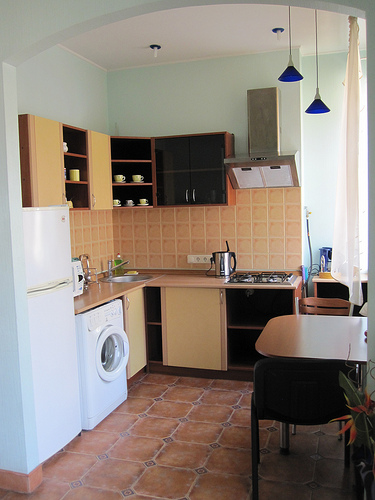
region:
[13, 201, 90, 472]
white refrigerator in the kitchen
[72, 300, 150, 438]
white dish washer in the kitch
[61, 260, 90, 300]
white microwave in the kitchen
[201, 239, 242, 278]
black and silver coffee maker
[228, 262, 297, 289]
black and silver gas stove in the kitchen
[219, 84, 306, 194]
white and silver vents over the stove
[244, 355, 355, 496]
black chair next to the table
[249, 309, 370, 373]
small wooden dining table by the window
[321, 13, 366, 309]
white curtains covering the windows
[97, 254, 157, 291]
silver and round sink on the counter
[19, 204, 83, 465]
a white upright two door refrigerator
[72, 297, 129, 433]
a white front load washing machine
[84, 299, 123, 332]
a white control panel with many buttons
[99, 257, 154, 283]
a silver kitchen sink and faucet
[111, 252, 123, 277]
a clear bottle of bright green soap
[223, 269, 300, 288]
stove burners set into a counter top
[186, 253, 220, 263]
a white electrical outlet in the wall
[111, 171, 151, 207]
yellow tea cups and saucers on a sheves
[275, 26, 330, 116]
blue lights hang down from the ceiling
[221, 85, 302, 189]
a silver stove vent hangs from a wall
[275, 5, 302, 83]
white and blue light fixture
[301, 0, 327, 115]
white and blue light fixture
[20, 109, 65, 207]
brown kitchen shelf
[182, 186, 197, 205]
kitchen shelf door handles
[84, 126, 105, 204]
brown kitchen shelf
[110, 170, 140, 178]
two teacups in kitchen shelf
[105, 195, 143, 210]
three teacups in kitchen shelf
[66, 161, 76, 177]
mug in kitchen shelf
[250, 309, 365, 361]
wooden table in kitchen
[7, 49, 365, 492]
a kitchen room scene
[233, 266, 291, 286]
gas stove cooktop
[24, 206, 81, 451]
a white refrigerator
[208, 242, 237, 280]
silver and black coffee pot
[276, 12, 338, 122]
two blue hanging lights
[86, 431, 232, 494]
brown, red, and blue floor tiles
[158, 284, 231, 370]
brown kitchen cabinet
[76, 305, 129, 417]
white clothes washer with door open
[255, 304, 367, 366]
shiny wood table top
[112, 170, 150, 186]
two yellow tea mugs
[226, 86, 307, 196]
range hood above stove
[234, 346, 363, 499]
black chair at the table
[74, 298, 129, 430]
washing machine under the counter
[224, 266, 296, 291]
four burner stove top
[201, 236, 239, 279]
silver hot water kettle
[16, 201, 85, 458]
white refrigerator and freezer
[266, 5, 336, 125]
blue and white ceiling lights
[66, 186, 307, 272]
tan tiled backsplash above counter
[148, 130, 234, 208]
cupboard with glass doors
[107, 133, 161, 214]
teacups in open cabinet